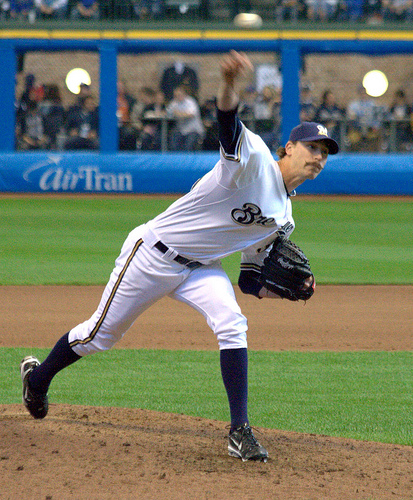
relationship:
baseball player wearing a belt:
[18, 48, 340, 465] [151, 227, 171, 307]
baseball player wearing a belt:
[18, 48, 340, 465] [157, 242, 198, 273]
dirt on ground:
[2, 404, 411, 500] [111, 412, 162, 484]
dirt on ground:
[2, 404, 411, 500] [109, 399, 232, 498]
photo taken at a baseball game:
[69, 199, 281, 328] [1, 1, 409, 487]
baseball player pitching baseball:
[18, 48, 340, 465] [230, 8, 261, 29]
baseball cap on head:
[289, 120, 340, 155] [294, 141, 330, 184]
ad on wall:
[20, 155, 133, 195] [0, 152, 413, 196]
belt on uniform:
[140, 236, 222, 266] [26, 93, 343, 427]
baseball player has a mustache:
[18, 48, 340, 465] [304, 159, 325, 171]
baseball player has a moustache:
[18, 48, 340, 465] [299, 155, 330, 174]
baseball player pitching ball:
[18, 48, 340, 465] [236, 12, 260, 28]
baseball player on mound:
[90, 106, 360, 429] [4, 395, 408, 495]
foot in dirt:
[226, 422, 269, 462] [4, 395, 411, 498]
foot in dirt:
[20, 352, 50, 421] [2, 276, 412, 355]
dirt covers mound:
[2, 404, 411, 495] [10, 386, 412, 497]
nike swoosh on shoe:
[229, 432, 243, 453] [224, 425, 268, 465]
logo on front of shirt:
[229, 201, 275, 228] [156, 122, 299, 268]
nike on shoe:
[229, 435, 243, 451] [227, 426, 268, 464]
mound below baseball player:
[14, 445, 404, 496] [18, 48, 340, 465]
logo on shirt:
[202, 187, 296, 246] [105, 63, 341, 288]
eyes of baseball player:
[305, 141, 332, 161] [18, 48, 340, 465]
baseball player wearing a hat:
[18, 48, 340, 465] [287, 119, 348, 153]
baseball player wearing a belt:
[18, 48, 340, 465] [150, 239, 205, 269]